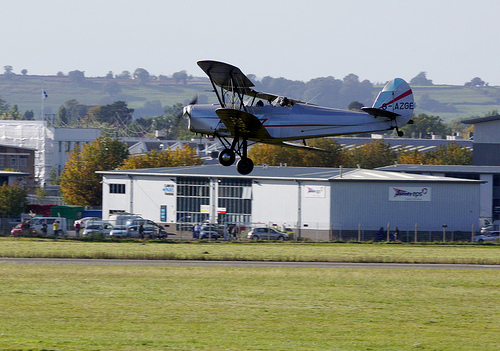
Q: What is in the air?
A: Airplane?.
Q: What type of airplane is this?
A: Biplane.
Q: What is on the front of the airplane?
A: Propeller.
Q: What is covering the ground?
A: Grass.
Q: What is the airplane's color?
A: Silver.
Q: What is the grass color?
A: Green.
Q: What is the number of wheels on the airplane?
A: 2.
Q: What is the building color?
A: White.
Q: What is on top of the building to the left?
A: Flag.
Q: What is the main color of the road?
A: Gray.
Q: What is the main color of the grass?
A: Green.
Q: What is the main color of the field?
A: Green.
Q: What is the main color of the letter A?
A: Black.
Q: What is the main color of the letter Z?
A: Black.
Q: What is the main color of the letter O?
A: Black.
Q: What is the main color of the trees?
A: Green.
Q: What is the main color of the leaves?
A: Green.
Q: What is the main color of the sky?
A: Gray.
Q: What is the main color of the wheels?
A: Black.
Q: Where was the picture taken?
A: At an airport.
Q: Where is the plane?
A: In the air.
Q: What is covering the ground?
A: Grass.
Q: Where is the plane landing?
A: On runway.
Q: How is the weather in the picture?
A: Sunny.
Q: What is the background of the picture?
A: A hill.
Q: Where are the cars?
A: In parking lot.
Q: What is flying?
A: A plane.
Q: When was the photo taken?
A: Daytime.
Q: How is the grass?
A: Short.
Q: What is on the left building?
A: A flag.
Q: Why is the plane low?
A: It's landing.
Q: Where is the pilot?
A: In the plane.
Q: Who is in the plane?
A: A pilot.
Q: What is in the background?
A: Hills.